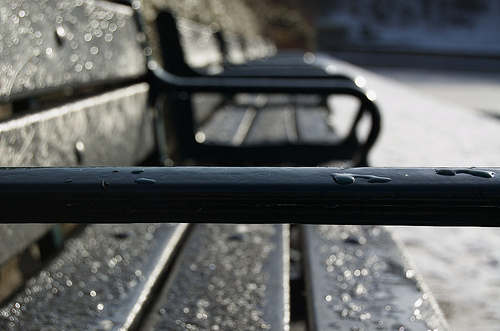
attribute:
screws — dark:
[39, 15, 141, 202]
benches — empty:
[140, 0, 392, 171]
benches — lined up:
[24, 57, 486, 311]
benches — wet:
[162, 5, 376, 111]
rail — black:
[2, 159, 497, 233]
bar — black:
[0, 165, 499, 227]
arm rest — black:
[4, 165, 499, 227]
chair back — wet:
[0, 0, 155, 270]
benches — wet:
[0, 0, 499, 330]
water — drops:
[328, 168, 393, 187]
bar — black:
[37, 169, 474, 220]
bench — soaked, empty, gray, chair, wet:
[5, 0, 459, 331]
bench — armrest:
[153, 0, 383, 168]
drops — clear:
[302, 178, 498, 198]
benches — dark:
[105, 1, 404, 183]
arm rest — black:
[2, 161, 472, 235]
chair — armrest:
[182, 17, 393, 164]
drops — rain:
[331, 169, 404, 196]